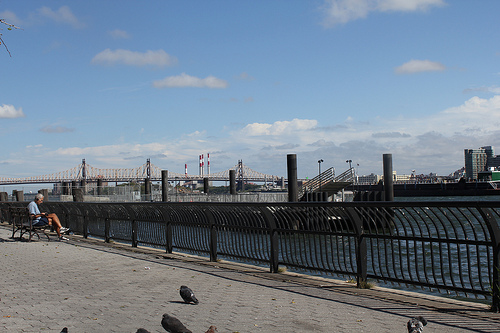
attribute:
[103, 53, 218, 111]
clouds — white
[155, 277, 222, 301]
bird — small, black, blacky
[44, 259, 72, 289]
sidewalk — gray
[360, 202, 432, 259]
fence — iron, black, metal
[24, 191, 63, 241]
man — sitting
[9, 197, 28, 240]
bench — wooden, metal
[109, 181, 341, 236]
barge — large, gray, long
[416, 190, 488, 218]
water — blue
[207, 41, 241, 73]
sky — cloudy, bluee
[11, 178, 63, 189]
bridge — big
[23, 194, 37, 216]
shirt — blue